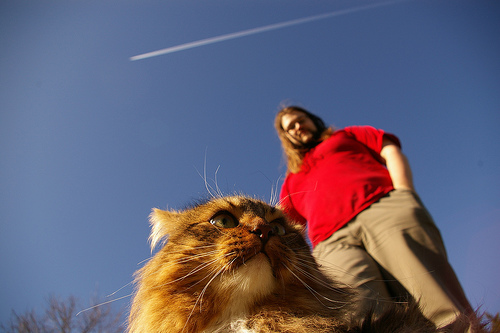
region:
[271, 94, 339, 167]
the man has long hair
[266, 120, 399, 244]
the man is wearing a short sleeve shirt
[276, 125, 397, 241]
the shirt is red in color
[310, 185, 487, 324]
the man is wearing long pants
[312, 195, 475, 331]
the pants are brown in color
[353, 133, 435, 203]
the man has his hand in his pocket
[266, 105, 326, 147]
the man is looking down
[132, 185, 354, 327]
a cat is in the foreground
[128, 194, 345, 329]
the cat is brown in color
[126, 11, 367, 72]
the plane is making a trail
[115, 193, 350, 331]
big yellow furry cat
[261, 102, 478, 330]
blonde man standing next to a cat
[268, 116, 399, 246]
red t-shirtof blonde man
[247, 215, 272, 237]
little brown nose of cat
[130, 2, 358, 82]
white comet in sky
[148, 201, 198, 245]
little right ear of cat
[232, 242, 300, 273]
little mouth of cat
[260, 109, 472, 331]
fat man standing with hands in his pockets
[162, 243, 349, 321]
white whiskers of yellow cat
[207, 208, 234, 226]
small yellow right eye of cat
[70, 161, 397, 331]
orange cat looking to the right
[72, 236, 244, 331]
white whiskers on face of cat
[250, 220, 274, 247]
cat nose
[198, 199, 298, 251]
yellow and black cat eyes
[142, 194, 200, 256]
orange cat ear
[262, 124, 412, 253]
red short sleeve cotton t-shirt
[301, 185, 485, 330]
tan cotton pants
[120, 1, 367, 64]
white line streak in sky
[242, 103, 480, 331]
man with long brown hair looking down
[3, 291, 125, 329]
bare brown tree branches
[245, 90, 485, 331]
man is looking down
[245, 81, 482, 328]
man is looking at cat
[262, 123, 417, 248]
man's shirt is red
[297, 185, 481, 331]
man's pants are brown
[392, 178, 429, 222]
man's hand in pocket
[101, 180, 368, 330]
the cat is orange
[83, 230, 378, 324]
cat's whiskers are white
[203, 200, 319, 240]
cat's eyes are yellow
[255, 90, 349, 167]
man's hair is blonde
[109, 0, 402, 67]
jet flying in air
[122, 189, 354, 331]
A fluffy cat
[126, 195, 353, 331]
A furry feline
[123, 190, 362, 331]
A brown kitty cat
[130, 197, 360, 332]
A domestic animal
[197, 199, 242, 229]
The left eye of the cat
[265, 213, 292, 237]
The right eye of the cat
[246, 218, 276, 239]
The pink and brown nose of the cat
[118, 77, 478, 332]
A male figure standing behind the cat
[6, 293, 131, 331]
The top of the tree branches with no leaves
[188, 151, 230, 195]
Thw white whiskers of the cat